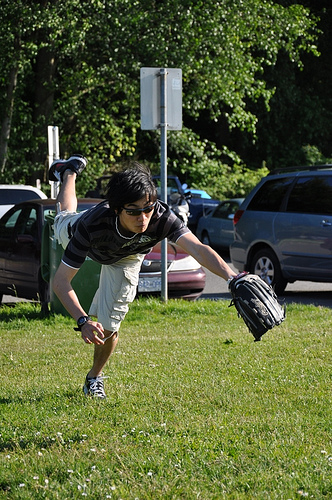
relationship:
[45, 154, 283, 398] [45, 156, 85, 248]
man has a leg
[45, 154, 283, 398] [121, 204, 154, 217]
man wearing sunglasses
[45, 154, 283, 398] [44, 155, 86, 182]
man has a shoe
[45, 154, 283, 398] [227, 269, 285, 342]
man wearing a catcher's mitt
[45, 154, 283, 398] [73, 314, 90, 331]
man wearing a watch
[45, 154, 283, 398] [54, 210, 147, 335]
man wearing shorts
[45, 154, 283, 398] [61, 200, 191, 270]
man wearing a shirt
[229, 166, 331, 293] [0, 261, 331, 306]
minivan in parking lot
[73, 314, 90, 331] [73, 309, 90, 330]
watch on h wrist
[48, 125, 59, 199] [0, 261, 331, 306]
sign on street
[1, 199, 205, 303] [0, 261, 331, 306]
car parked on road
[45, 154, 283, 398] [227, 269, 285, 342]
man holding catcher's mitt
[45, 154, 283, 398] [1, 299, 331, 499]
man standing in grass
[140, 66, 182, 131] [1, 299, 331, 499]
sign in grass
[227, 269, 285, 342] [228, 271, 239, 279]
catcher's mitt on hand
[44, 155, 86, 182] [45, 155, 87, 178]
shoe on h foot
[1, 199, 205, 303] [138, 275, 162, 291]
car has license plate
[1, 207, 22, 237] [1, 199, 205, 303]
window on car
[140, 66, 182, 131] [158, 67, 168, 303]
sign on pole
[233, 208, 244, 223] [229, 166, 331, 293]
tail light on minivan